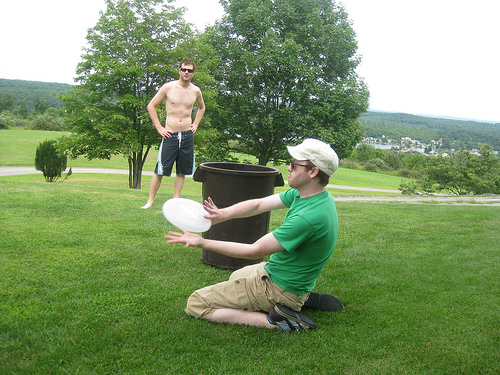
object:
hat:
[285, 137, 340, 176]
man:
[162, 137, 344, 333]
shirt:
[263, 187, 340, 296]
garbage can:
[193, 161, 284, 271]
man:
[139, 58, 207, 209]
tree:
[212, 1, 369, 166]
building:
[412, 140, 420, 146]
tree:
[357, 144, 385, 164]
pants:
[183, 261, 312, 322]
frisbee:
[161, 196, 213, 233]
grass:
[0, 337, 498, 375]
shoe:
[267, 303, 319, 334]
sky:
[377, 2, 499, 102]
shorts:
[153, 130, 195, 177]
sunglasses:
[181, 68, 193, 72]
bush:
[34, 140, 67, 182]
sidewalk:
[2, 166, 497, 204]